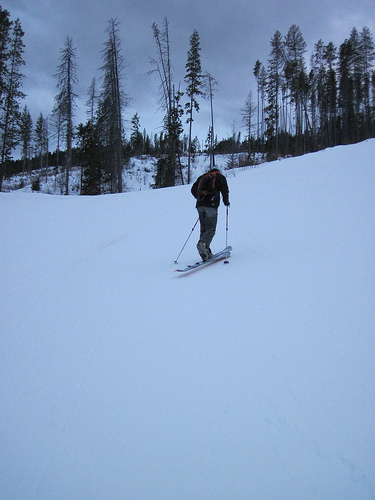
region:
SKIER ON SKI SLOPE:
[113, 152, 256, 281]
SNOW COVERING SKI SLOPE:
[10, 191, 345, 441]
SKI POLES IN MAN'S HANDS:
[161, 180, 267, 270]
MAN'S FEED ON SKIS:
[141, 217, 257, 288]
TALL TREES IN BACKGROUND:
[2, 12, 368, 197]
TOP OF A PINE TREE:
[171, 15, 227, 165]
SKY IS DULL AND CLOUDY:
[4, 0, 364, 128]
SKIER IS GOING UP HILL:
[128, 158, 260, 275]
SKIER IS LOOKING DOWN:
[192, 157, 245, 212]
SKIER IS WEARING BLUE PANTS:
[165, 203, 254, 277]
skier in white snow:
[167, 158, 240, 275]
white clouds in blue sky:
[34, 20, 55, 63]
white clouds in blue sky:
[135, 14, 145, 45]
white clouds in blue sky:
[198, 5, 233, 54]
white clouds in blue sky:
[219, 47, 236, 84]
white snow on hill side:
[15, 210, 55, 260]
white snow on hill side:
[86, 338, 154, 387]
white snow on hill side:
[203, 315, 251, 378]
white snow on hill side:
[240, 407, 280, 467]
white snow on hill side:
[257, 286, 307, 351]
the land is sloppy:
[40, 272, 326, 400]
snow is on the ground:
[67, 347, 225, 434]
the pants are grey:
[188, 206, 226, 245]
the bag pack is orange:
[189, 169, 224, 198]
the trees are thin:
[58, 68, 367, 132]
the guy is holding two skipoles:
[168, 185, 247, 271]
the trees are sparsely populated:
[7, 21, 367, 152]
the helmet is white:
[210, 161, 225, 170]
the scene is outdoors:
[9, 7, 372, 498]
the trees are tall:
[91, 24, 186, 172]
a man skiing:
[177, 164, 246, 285]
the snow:
[140, 326, 312, 446]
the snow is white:
[76, 308, 306, 449]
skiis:
[173, 261, 197, 280]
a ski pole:
[222, 205, 237, 238]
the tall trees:
[78, 93, 133, 187]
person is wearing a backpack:
[196, 171, 215, 196]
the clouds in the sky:
[207, 13, 267, 41]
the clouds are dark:
[55, 6, 111, 29]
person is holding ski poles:
[221, 200, 231, 211]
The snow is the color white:
[22, 329, 347, 475]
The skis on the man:
[166, 240, 240, 276]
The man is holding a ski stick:
[220, 195, 234, 266]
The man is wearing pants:
[193, 200, 221, 257]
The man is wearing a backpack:
[194, 168, 222, 198]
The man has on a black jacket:
[185, 171, 232, 210]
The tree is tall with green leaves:
[252, 27, 374, 165]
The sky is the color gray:
[48, 3, 343, 53]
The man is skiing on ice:
[127, 143, 273, 304]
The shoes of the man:
[192, 241, 219, 262]